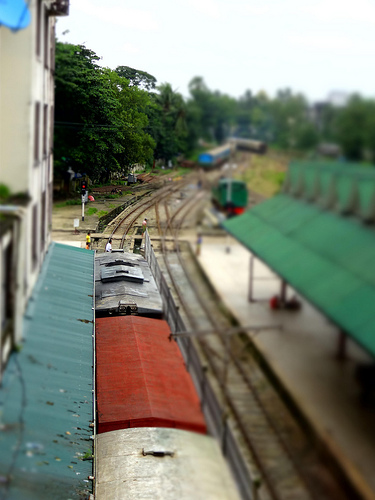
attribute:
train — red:
[91, 314, 219, 433]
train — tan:
[91, 423, 242, 496]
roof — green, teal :
[1, 240, 101, 493]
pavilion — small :
[228, 155, 372, 394]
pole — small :
[81, 190, 88, 222]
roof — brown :
[93, 254, 162, 313]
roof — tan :
[92, 425, 244, 498]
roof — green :
[226, 157, 372, 355]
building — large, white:
[9, 0, 75, 187]